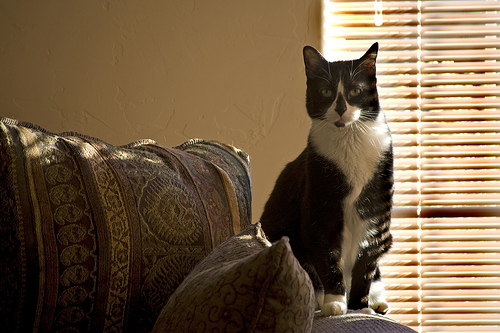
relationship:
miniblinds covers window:
[327, 4, 498, 310] [324, 1, 496, 330]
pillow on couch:
[150, 222, 312, 332] [0, 116, 415, 331]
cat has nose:
[254, 37, 400, 319] [329, 103, 359, 121]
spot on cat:
[334, 89, 346, 101] [254, 37, 400, 319]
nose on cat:
[329, 103, 359, 121] [254, 37, 400, 319]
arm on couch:
[308, 302, 430, 332] [0, 116, 415, 331]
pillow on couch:
[142, 240, 362, 318] [15, 107, 399, 325]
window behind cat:
[339, 13, 497, 324] [254, 37, 400, 319]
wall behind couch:
[0, 0, 325, 223] [0, 116, 415, 331]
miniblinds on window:
[320, 0, 497, 333] [324, 1, 496, 330]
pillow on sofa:
[150, 222, 312, 332] [3, 110, 258, 332]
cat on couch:
[254, 37, 400, 319] [0, 116, 415, 331]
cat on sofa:
[254, 37, 400, 319] [3, 110, 258, 332]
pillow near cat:
[150, 222, 312, 332] [254, 37, 400, 319]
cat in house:
[254, 37, 400, 319] [1, 0, 499, 330]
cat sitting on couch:
[254, 37, 400, 319] [0, 116, 415, 331]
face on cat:
[296, 48, 396, 148] [254, 37, 400, 319]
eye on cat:
[320, 86, 332, 98] [271, 41, 402, 305]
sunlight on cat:
[361, 218, 396, 251] [254, 37, 400, 319]